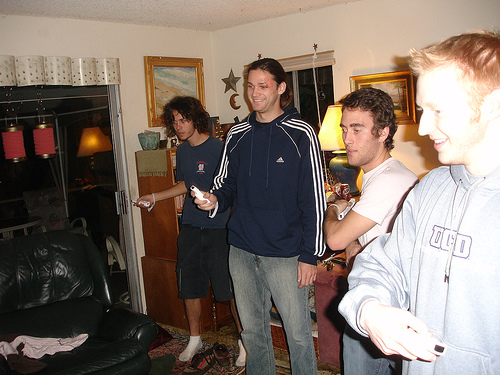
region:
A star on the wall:
[219, 68, 242, 91]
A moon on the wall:
[227, 93, 242, 112]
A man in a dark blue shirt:
[190, 56, 330, 373]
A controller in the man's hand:
[185, 184, 220, 216]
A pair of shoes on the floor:
[185, 340, 231, 373]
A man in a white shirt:
[323, 87, 418, 252]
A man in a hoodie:
[336, 30, 497, 374]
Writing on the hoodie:
[430, 225, 471, 258]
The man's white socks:
[177, 335, 247, 365]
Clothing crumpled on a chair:
[2, 330, 89, 370]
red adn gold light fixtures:
[1, 88, 59, 164]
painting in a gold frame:
[145, 57, 206, 127]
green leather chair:
[0, 228, 159, 374]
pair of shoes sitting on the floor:
[179, 342, 229, 373]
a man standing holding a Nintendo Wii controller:
[135, 96, 243, 366]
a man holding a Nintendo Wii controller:
[188, 59, 325, 374]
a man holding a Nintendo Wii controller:
[319, 87, 414, 373]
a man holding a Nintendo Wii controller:
[337, 31, 498, 372]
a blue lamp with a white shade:
[316, 105, 360, 201]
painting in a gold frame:
[350, 69, 415, 126]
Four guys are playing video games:
[122, 23, 497, 371]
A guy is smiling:
[235, 51, 295, 113]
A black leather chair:
[0, 225, 161, 371]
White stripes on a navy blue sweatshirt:
[200, 101, 330, 261]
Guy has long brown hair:
[151, 90, 213, 146]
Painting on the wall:
[136, 45, 211, 130]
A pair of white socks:
[172, 327, 252, 367]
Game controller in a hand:
[182, 180, 222, 220]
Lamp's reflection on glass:
[66, 115, 116, 190]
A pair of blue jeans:
[220, 240, 321, 371]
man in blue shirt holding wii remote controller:
[184, 58, 326, 373]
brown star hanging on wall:
[220, 67, 242, 95]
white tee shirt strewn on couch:
[2, 328, 89, 367]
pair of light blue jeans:
[228, 245, 318, 374]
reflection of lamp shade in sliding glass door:
[75, 124, 114, 163]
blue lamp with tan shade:
[314, 102, 362, 197]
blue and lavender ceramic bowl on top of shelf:
[135, 127, 160, 149]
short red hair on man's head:
[402, 29, 496, 174]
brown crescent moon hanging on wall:
[227, 91, 242, 111]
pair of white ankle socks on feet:
[177, 330, 247, 365]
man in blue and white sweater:
[198, 61, 327, 280]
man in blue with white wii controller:
[128, 91, 237, 373]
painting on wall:
[139, 46, 211, 130]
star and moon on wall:
[215, 61, 247, 118]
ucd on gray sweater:
[423, 215, 475, 265]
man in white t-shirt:
[325, 88, 410, 264]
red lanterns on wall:
[3, 119, 58, 164]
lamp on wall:
[77, 122, 117, 164]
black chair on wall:
[0, 241, 172, 371]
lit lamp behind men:
[305, 90, 354, 167]